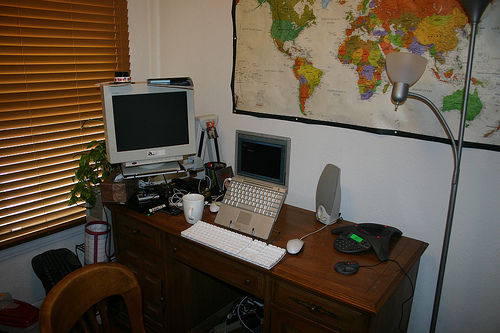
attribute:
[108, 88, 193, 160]
screen — large, square shaped, black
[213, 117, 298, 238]
laptop — small, square shaped, grey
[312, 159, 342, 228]
speaker — grey, small, wide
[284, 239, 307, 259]
mouse — small, round, white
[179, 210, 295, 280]
keyboard — white, long, plastic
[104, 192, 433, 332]
desk — large, wide, wooden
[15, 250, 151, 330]
chair — wooden, large, short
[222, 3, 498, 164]
map — large, wide, paper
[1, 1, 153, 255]
window — large, brown, shaded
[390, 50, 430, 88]
lamp shade — small, white